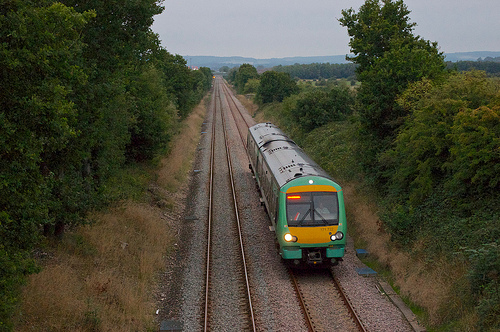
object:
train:
[244, 122, 349, 272]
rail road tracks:
[158, 68, 426, 331]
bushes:
[0, 0, 499, 331]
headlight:
[282, 233, 298, 242]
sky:
[149, 0, 499, 71]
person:
[315, 203, 331, 219]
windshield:
[285, 191, 339, 226]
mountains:
[174, 50, 499, 72]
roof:
[247, 121, 337, 187]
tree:
[334, 0, 459, 139]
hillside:
[347, 143, 499, 331]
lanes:
[204, 76, 346, 330]